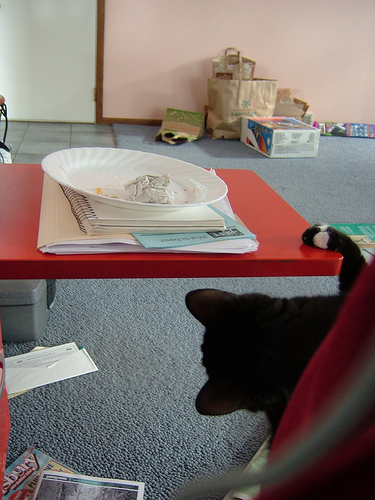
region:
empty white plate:
[28, 140, 233, 218]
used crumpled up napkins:
[86, 154, 214, 226]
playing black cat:
[185, 225, 354, 432]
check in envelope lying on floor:
[0, 312, 95, 404]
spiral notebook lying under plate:
[24, 164, 244, 259]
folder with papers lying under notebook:
[16, 164, 242, 256]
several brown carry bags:
[145, 45, 324, 154]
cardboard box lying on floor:
[223, 114, 321, 167]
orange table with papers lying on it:
[0, 123, 325, 288]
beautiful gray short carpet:
[49, 312, 193, 465]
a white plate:
[32, 123, 247, 212]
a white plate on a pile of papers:
[41, 122, 318, 263]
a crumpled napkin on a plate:
[46, 116, 250, 234]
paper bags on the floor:
[140, 33, 330, 143]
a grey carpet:
[109, 118, 370, 414]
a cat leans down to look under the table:
[180, 211, 371, 493]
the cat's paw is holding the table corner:
[133, 222, 373, 434]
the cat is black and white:
[194, 214, 373, 498]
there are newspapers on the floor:
[9, 431, 124, 499]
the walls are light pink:
[128, 6, 373, 139]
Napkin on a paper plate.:
[87, 137, 236, 221]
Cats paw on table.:
[280, 206, 367, 305]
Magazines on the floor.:
[7, 438, 140, 498]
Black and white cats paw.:
[252, 207, 350, 272]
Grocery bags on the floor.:
[153, 31, 286, 182]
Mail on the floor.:
[7, 328, 114, 396]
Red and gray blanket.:
[254, 242, 372, 491]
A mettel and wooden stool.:
[6, 79, 23, 171]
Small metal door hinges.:
[76, 78, 102, 139]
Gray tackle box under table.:
[0, 227, 92, 350]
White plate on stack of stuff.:
[34, 135, 235, 214]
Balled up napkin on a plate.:
[120, 157, 183, 203]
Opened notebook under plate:
[54, 176, 223, 234]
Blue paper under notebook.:
[124, 196, 254, 246]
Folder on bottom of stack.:
[35, 153, 247, 256]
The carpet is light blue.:
[0, 119, 374, 498]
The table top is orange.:
[0, 156, 348, 287]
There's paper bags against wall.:
[148, 43, 301, 144]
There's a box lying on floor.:
[235, 108, 323, 160]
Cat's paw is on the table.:
[298, 212, 364, 283]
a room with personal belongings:
[48, 45, 340, 470]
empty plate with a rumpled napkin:
[33, 127, 239, 218]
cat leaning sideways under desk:
[169, 201, 358, 441]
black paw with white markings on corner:
[285, 205, 360, 286]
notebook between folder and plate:
[30, 135, 265, 270]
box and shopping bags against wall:
[147, 20, 318, 155]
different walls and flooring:
[45, 22, 151, 137]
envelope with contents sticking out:
[7, 331, 108, 399]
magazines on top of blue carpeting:
[4, 384, 180, 495]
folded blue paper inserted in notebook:
[125, 216, 269, 258]